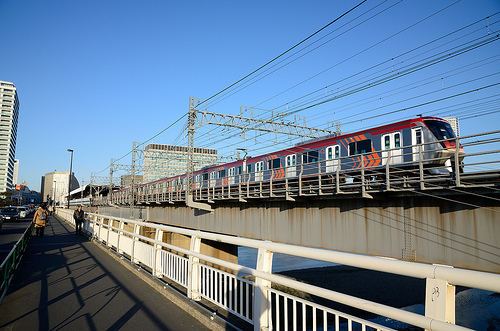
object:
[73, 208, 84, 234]
clothing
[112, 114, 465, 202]
train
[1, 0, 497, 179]
sky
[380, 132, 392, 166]
doors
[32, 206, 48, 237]
people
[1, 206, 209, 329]
sidewalk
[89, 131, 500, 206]
rail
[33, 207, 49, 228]
jacket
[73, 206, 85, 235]
person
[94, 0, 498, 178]
wire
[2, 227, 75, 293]
shadow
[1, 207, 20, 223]
cars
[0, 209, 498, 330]
bridge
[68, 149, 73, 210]
lamp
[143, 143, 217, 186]
building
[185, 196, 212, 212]
steel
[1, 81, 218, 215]
city